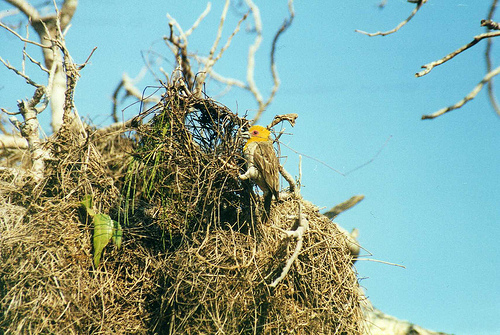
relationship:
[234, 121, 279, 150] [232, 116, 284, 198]
head on bird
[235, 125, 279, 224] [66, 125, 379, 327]
bird in grass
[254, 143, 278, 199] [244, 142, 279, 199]
feathers on body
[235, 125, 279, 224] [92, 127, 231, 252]
bird in nest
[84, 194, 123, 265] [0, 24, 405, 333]
leaf on nest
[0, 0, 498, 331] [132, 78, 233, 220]
tree behind nest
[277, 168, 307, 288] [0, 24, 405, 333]
branch in nest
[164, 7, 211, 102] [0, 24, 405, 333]
branch in nest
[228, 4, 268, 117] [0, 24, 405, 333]
branch in nest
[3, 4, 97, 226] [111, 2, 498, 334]
tree next to trees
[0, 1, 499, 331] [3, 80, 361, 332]
sky above nest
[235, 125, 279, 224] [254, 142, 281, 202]
bird has wing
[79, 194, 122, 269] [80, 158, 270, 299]
leaf on grass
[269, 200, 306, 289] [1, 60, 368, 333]
stick branch on weed grass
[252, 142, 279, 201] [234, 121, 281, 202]
feathers of bird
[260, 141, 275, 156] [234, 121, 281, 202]
feather of bird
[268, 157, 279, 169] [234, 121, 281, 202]
feather of bird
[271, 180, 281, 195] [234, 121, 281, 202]
feather of bird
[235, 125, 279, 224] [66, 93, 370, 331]
bird on nest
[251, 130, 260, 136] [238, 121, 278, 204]
eye of bird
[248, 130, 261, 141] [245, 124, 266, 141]
eye on head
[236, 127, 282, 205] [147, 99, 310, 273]
bird and nest